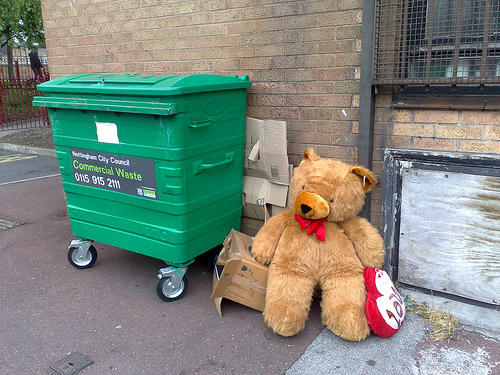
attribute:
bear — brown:
[207, 150, 385, 303]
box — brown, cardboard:
[178, 246, 257, 306]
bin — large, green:
[42, 88, 212, 234]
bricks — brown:
[240, 30, 417, 235]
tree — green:
[7, 16, 53, 63]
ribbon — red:
[275, 204, 340, 234]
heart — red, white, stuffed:
[369, 267, 461, 346]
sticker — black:
[64, 144, 175, 188]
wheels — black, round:
[81, 240, 254, 341]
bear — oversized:
[245, 171, 423, 370]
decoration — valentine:
[357, 248, 420, 327]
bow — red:
[292, 204, 347, 242]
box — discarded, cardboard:
[172, 221, 294, 337]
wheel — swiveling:
[133, 257, 185, 294]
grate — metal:
[365, 41, 483, 81]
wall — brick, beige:
[108, 0, 406, 124]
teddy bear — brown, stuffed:
[245, 142, 393, 349]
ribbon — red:
[288, 211, 335, 245]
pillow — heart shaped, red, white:
[357, 263, 409, 342]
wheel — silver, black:
[156, 261, 190, 306]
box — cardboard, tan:
[204, 229, 277, 320]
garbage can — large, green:
[28, 69, 256, 299]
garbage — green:
[28, 67, 253, 267]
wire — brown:
[370, 0, 484, 99]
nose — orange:
[287, 190, 331, 226]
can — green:
[27, 66, 251, 308]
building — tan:
[31, 0, 481, 310]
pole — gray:
[355, 1, 381, 221]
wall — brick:
[38, 1, 482, 299]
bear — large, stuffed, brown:
[249, 147, 387, 347]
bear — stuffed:
[252, 141, 395, 349]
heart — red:
[362, 263, 409, 342]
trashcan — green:
[27, 68, 256, 309]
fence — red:
[2, 58, 51, 136]